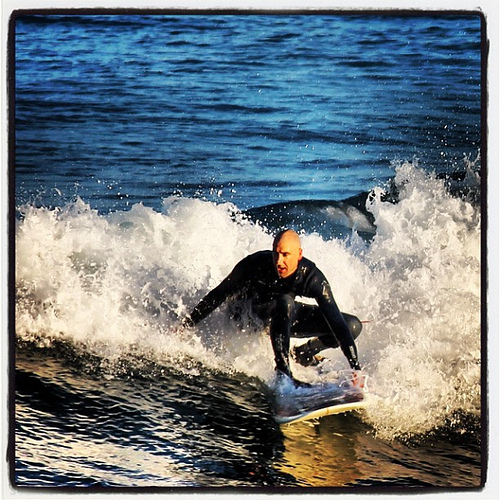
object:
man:
[170, 228, 367, 419]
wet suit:
[183, 250, 363, 372]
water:
[14, 12, 481, 486]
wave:
[9, 138, 481, 444]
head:
[271, 227, 303, 278]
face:
[272, 235, 296, 278]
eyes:
[273, 251, 291, 259]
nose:
[275, 255, 282, 267]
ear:
[299, 247, 304, 261]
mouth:
[277, 265, 288, 273]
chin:
[278, 272, 287, 279]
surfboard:
[271, 353, 368, 425]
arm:
[307, 270, 358, 369]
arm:
[185, 253, 256, 327]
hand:
[347, 368, 368, 388]